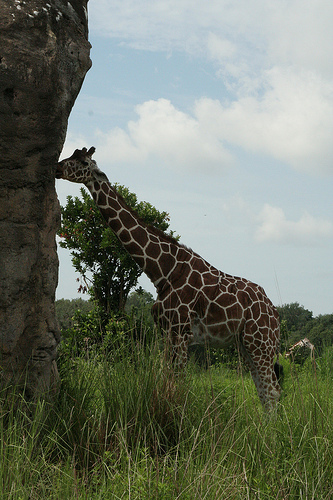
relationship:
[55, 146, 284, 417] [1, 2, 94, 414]
giraffe standing by wall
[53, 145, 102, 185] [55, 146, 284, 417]
head of giraffe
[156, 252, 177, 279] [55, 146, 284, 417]
spot on giraffe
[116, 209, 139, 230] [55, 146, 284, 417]
spot on giraffe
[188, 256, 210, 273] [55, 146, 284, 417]
spot on giraffe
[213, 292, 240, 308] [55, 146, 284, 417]
spot on giraffe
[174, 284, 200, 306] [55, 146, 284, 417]
spot on giraffe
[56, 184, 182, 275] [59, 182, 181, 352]
leaves of tree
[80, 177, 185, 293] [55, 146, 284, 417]
neck of giraffe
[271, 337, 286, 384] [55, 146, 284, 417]
tail of giraffe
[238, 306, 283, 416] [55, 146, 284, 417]
hind leg of giraffe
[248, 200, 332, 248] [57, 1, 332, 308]
cloud in sky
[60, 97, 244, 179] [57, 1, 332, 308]
cloud in sky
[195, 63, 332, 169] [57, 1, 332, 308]
cloud in sky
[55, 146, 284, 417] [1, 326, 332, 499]
giraffe standing in grass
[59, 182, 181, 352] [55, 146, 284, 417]
tree behind giraffe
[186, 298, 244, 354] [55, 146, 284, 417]
belly of giraffe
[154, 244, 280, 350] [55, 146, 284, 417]
body of giraffe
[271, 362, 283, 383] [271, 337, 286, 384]
hair on tail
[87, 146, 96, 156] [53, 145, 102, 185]
horn on head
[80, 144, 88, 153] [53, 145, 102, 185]
horn on head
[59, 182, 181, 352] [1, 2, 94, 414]
tree close to wall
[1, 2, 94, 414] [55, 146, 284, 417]
wall in front of giraffe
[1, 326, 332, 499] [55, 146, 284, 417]
grass around giraffe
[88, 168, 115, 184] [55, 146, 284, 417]
ear of giraffe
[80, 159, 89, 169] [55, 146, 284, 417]
eye of giraffe